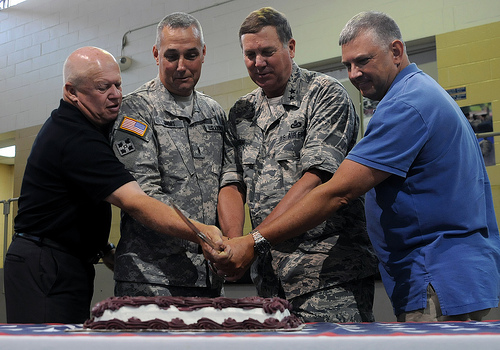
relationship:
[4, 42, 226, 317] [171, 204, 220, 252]
man holds knife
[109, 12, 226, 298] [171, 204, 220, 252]
man holds knife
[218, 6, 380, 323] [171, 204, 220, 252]
man holds knife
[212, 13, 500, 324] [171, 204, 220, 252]
man holds knife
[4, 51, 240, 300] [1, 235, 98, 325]
man has pants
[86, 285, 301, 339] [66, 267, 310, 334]
icing on cake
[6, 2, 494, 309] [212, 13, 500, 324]
wall behind man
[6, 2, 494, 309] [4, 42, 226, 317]
wall behind man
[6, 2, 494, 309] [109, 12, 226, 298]
wall behind man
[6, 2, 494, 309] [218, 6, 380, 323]
wall behind man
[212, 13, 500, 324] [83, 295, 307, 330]
man cutting cake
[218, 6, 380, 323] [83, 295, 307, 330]
man cutting cake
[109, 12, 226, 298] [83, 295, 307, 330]
man cutting cake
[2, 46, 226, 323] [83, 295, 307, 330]
man cutting cake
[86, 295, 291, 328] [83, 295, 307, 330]
icing on cake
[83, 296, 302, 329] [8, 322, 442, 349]
cake on table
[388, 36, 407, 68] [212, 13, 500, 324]
ear of man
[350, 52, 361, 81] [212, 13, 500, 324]
nose of man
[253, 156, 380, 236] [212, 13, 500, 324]
arm of man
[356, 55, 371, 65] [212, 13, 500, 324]
eye of man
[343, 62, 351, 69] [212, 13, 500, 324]
eye of man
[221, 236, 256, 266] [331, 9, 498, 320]
hand of man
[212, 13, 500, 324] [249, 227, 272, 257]
man wearing silver watch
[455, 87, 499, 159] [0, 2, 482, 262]
pictures hanging wall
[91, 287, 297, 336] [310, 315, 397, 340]
cake on top of table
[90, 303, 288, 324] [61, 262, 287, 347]
frosting on top of cake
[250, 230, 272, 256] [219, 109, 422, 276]
silver watch worn on arm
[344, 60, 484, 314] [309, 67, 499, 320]
man wearing shirt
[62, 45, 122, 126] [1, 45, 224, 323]
head on top of body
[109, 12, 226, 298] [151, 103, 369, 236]
man wearing fatigues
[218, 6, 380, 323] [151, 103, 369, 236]
man wearing fatigues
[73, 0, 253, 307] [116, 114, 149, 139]
man has flag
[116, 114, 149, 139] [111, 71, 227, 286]
flag on shirt